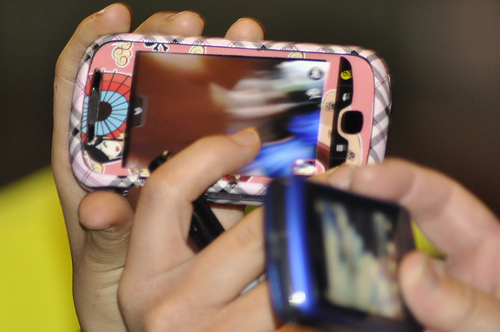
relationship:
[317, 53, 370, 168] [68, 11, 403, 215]
panel on phone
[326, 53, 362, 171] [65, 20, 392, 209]
panel at bottom of cell phone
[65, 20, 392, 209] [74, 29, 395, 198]
cell phone has trim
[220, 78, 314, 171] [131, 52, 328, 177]
coral in background of coral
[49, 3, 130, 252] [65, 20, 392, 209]
finger holding cell phone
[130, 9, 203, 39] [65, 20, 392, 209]
finger holding cell phone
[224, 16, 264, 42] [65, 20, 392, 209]
finger holding cell phone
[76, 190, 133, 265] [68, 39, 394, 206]
finger holding device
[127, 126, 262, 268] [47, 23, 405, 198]
finger holding phone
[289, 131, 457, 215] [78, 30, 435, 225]
finger holding phone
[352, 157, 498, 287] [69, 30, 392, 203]
finger holding phone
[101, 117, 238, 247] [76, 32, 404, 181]
finger holding phone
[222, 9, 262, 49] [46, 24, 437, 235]
finger holding phone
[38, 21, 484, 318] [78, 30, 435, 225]
hand holding phone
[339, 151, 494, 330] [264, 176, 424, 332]
hand holding camera